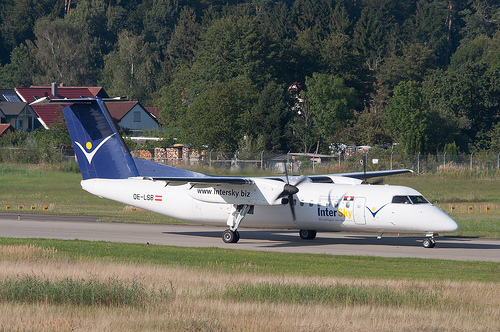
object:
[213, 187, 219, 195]
blue letter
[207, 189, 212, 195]
blue letter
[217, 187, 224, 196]
blue letter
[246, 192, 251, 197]
blue letter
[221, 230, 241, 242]
wheel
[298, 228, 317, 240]
wheel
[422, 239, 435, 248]
wheel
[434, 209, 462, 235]
nose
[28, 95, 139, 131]
roof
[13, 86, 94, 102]
roof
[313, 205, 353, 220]
name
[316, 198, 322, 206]
passenger windows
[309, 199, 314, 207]
passenger windows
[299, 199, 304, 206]
passenger windows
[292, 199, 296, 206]
passenger windows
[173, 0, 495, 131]
leaves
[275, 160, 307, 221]
propeller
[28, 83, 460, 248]
airplane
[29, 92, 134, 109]
tailwing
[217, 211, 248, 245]
landing gear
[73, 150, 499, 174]
fencing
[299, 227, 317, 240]
wheels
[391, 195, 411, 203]
windows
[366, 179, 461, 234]
cockpit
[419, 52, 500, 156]
trees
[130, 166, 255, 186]
wing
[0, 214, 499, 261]
tarmac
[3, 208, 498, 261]
airport runway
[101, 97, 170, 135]
house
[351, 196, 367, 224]
door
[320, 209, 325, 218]
letter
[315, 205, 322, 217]
letter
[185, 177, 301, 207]
engine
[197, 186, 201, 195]
letter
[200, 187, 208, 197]
letter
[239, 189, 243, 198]
letter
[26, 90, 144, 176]
tail